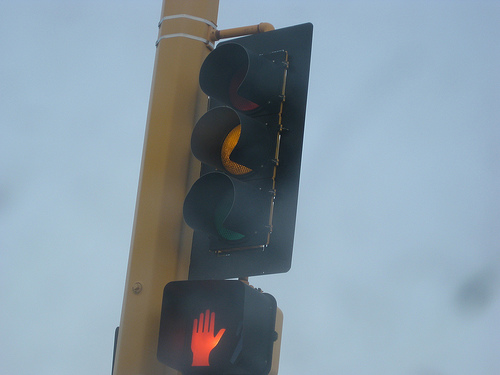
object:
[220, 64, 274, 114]
light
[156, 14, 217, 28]
white straps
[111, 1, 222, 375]
pole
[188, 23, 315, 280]
frame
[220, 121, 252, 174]
lights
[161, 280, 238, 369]
sign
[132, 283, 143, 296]
bolt